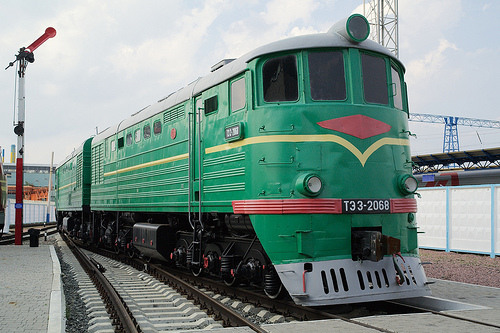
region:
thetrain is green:
[260, 157, 286, 184]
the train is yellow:
[288, 134, 313, 141]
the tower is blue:
[447, 121, 457, 146]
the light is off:
[308, 178, 318, 190]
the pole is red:
[11, 169, 26, 191]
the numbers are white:
[356, 195, 387, 212]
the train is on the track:
[173, 252, 230, 290]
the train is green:
[16, 69, 425, 331]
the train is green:
[24, 50, 432, 291]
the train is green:
[47, 74, 452, 313]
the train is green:
[22, 52, 397, 330]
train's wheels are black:
[50, 213, 296, 296]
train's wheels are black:
[42, 208, 302, 288]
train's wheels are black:
[40, 199, 259, 299]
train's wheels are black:
[36, 205, 281, 310]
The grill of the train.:
[278, 262, 450, 303]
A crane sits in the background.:
[414, 108, 494, 148]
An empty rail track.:
[67, 240, 216, 326]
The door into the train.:
[184, 99, 207, 224]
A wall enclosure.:
[429, 183, 498, 254]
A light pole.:
[3, 45, 30, 239]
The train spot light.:
[350, 220, 407, 268]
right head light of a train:
[299, 169, 331, 203]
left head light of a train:
[395, 170, 424, 197]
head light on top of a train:
[330, 6, 381, 56]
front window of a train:
[245, 41, 420, 116]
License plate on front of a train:
[335, 193, 398, 220]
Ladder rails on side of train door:
[177, 100, 218, 252]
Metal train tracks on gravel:
[77, 273, 166, 315]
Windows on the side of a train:
[101, 114, 166, 151]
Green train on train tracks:
[102, 8, 459, 331]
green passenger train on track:
[48, 12, 440, 315]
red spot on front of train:
[310, 110, 395, 144]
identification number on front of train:
[337, 195, 392, 215]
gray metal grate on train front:
[271, 252, 436, 310]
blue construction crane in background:
[411, 108, 498, 157]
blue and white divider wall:
[412, 181, 498, 265]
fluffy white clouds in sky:
[2, 2, 497, 167]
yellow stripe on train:
[95, 129, 415, 179]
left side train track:
[57, 224, 273, 331]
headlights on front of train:
[296, 168, 421, 200]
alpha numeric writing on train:
[335, 192, 397, 219]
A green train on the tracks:
[55, 13, 430, 311]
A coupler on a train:
[353, 228, 400, 263]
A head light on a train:
[302, 173, 324, 196]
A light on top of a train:
[331, 13, 372, 45]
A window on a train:
[304, 44, 346, 100]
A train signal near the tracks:
[5, 27, 57, 242]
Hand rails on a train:
[183, 107, 203, 230]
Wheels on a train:
[167, 228, 290, 303]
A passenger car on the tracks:
[54, 132, 89, 246]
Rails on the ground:
[58, 223, 498, 332]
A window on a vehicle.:
[261, 53, 302, 108]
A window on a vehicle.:
[303, 48, 349, 101]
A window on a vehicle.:
[356, 51, 388, 108]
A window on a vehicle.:
[388, 66, 405, 108]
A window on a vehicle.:
[349, 17, 366, 40]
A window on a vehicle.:
[204, 94, 223, 113]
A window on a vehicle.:
[150, 117, 163, 133]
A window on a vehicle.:
[141, 125, 151, 137]